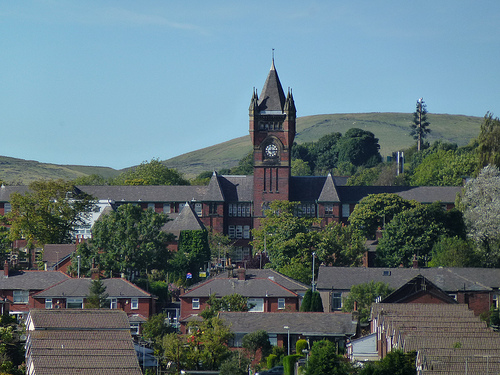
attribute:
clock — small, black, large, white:
[260, 135, 283, 166]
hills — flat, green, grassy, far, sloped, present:
[1, 111, 500, 188]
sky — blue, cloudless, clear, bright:
[2, 2, 499, 171]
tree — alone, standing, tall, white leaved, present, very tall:
[407, 95, 433, 152]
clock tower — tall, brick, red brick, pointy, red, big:
[248, 46, 299, 258]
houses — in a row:
[1, 260, 500, 343]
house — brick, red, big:
[178, 266, 299, 343]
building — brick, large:
[206, 47, 341, 286]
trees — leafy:
[349, 192, 474, 268]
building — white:
[45, 197, 117, 240]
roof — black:
[180, 278, 299, 300]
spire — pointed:
[269, 46, 278, 72]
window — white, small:
[189, 299, 202, 311]